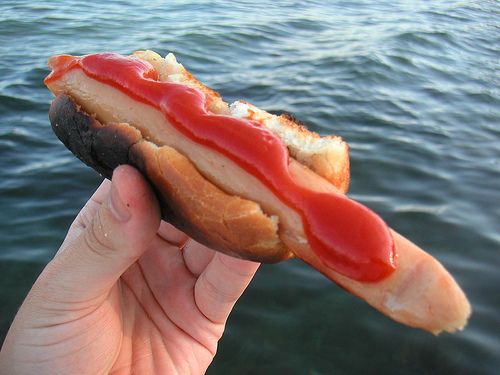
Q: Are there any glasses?
A: No, there are no glasses.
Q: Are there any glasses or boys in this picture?
A: No, there are no glasses or boys.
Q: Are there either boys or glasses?
A: No, there are no glasses or boys.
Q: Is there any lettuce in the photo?
A: No, there is no lettuce.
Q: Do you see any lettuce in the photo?
A: No, there is no lettuce.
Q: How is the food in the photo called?
A: The food is a bun.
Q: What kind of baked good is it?
A: The food is a bun.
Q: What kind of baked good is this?
A: This is a bun.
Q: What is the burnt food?
A: The food is a bun.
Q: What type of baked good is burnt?
A: The baked good is a bun.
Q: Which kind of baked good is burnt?
A: The baked good is a bun.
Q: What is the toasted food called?
A: The food is a bun.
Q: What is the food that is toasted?
A: The food is a bun.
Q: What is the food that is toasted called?
A: The food is a bun.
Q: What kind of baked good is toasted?
A: The baked good is a bun.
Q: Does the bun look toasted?
A: Yes, the bun is toasted.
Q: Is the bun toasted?
A: Yes, the bun is toasted.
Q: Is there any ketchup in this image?
A: Yes, there is ketchup.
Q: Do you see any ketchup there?
A: Yes, there is ketchup.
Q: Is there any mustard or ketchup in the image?
A: Yes, there is ketchup.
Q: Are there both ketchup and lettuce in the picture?
A: No, there is ketchup but no lettuce.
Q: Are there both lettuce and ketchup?
A: No, there is ketchup but no lettuce.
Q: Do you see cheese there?
A: No, there is no cheese.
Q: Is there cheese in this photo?
A: No, there is no cheese.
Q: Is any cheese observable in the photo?
A: No, there is no cheese.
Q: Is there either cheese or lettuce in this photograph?
A: No, there are no cheese or lettuce.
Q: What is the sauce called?
A: The sauce is ketchup.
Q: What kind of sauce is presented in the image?
A: The sauce is ketchup.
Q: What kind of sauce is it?
A: The sauce is ketchup.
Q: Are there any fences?
A: No, there are no fences.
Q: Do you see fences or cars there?
A: No, there are no fences or cars.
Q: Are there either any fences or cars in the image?
A: No, there are no fences or cars.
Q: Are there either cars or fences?
A: No, there are no fences or cars.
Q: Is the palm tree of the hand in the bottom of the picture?
A: Yes, the palm is in the bottom of the image.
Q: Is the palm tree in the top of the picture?
A: No, the palm tree is in the bottom of the image.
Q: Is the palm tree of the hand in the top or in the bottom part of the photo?
A: The palm tree is in the bottom of the image.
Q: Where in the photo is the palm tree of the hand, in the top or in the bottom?
A: The palm tree is in the bottom of the image.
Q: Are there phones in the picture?
A: No, there are no phones.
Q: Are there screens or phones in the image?
A: No, there are no phones or screens.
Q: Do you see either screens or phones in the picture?
A: No, there are no phones or screens.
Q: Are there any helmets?
A: No, there are no helmets.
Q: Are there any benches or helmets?
A: No, there are no helmets or benches.